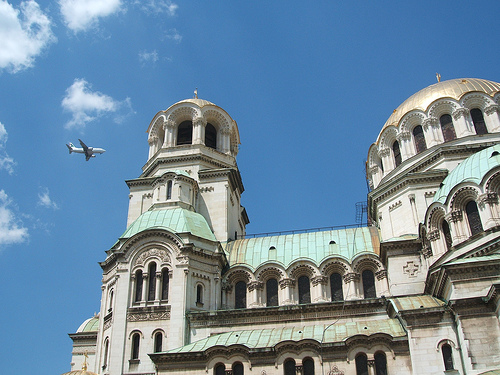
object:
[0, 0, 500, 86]
sky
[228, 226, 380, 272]
roof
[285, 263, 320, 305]
window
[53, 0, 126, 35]
cloud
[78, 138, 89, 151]
wing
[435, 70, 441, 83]
tip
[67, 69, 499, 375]
building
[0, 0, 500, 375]
picture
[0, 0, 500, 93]
day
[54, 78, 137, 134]
clouds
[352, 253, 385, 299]
windows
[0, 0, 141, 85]
sun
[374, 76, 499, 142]
dome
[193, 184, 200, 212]
ladder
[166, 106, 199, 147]
arches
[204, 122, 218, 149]
doors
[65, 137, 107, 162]
airplane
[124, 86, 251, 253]
tower